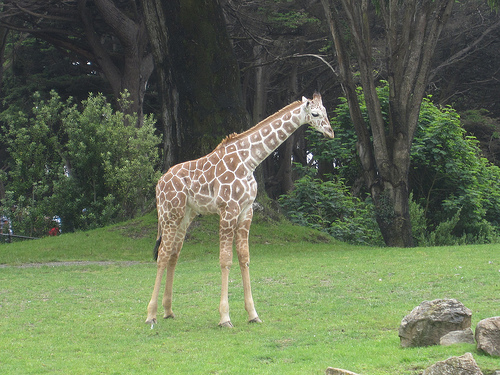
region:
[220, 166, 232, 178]
brown spot on a giraffe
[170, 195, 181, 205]
brown spot on a giraffe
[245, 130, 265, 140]
brown spot on a giraffe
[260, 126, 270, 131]
brown spot on a giraffe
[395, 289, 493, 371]
large gray stones on the ground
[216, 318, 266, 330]
black hooves on the grass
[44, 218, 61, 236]
a person wearing a red shirt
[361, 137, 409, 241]
dark gray bark on a tree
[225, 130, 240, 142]
a short brown mane on a back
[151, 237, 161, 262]
black hair on a tail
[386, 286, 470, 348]
rocks on the ground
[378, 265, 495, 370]
rocks on the ground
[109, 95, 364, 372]
a giraffe at the park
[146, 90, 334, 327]
the giraffe standing on the grass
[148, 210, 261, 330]
the giraffe's four legs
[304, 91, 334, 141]
the head of the giraffe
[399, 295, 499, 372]
the large rocks near the giraffe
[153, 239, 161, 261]
the black hair at the end of the giraffe's tail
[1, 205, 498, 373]
the green grass all around the giraffe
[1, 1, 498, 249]
the trees behind the giraffe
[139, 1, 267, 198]
the thick tree trunk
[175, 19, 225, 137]
the moss growing on the tree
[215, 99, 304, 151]
the mane on the back of the giraffe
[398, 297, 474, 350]
A large gray rock.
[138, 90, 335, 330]
A young giraffe.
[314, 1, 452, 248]
A large brown tree trunk.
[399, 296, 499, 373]
A group of large rocks.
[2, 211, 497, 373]
A big grassy area.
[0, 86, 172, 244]
A grouping of small trees.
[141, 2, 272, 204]
A large mossy tree trunk.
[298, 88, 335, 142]
A giraffe head.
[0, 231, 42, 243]
A wooden fence.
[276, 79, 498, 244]
A grouping of small trees.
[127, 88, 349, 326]
A giraffe on green grass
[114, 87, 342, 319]
a giraffe in a park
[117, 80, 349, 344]
a giraffe in a zoo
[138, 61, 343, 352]
a giraffe near a tree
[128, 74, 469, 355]
a giraffe near a rock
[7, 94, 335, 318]
a bush near a giraffe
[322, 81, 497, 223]
a bush behind a tree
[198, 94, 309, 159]
a mane on a giraffe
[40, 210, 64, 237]
a person in the distance